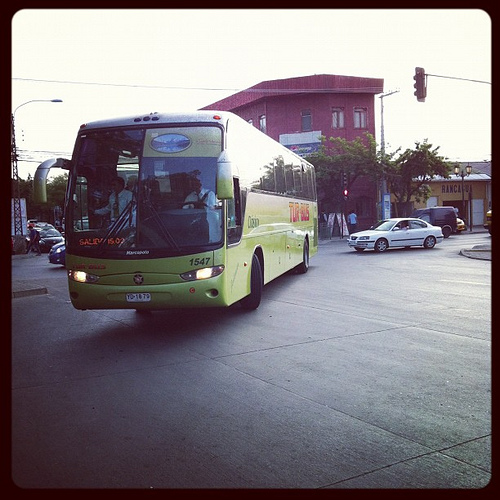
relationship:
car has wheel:
[348, 215, 446, 254] [375, 238, 389, 253]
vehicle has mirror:
[63, 111, 317, 317] [212, 149, 239, 201]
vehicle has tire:
[63, 111, 317, 317] [239, 254, 262, 310]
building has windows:
[202, 74, 385, 228] [244, 105, 371, 141]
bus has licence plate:
[63, 111, 317, 317] [123, 290, 154, 307]